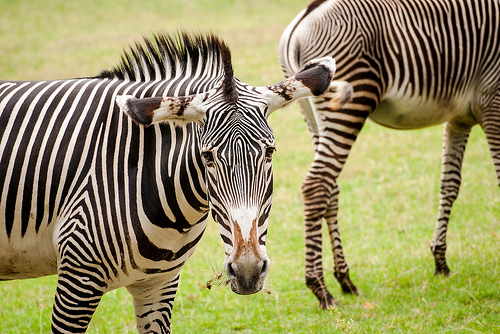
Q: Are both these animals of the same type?
A: Yes, all the animals are zebras.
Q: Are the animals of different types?
A: No, all the animals are zebras.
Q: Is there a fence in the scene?
A: No, there are no fences.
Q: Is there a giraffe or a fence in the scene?
A: No, there are no fences or giraffes.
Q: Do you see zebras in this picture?
A: Yes, there is a zebra.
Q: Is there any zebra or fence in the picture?
A: Yes, there is a zebra.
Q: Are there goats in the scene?
A: No, there are no goats.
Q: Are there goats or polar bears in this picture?
A: No, there are no goats or polar bears.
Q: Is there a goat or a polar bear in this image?
A: No, there are no goats or polar bears.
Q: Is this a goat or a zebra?
A: This is a zebra.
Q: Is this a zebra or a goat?
A: This is a zebra.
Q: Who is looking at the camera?
A: The zebra is looking at the camera.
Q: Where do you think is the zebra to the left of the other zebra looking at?
A: The zebra is looking at the camera.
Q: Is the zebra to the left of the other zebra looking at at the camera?
A: Yes, the zebra is looking at the camera.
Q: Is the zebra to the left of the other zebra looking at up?
A: No, the zebra is looking at the camera.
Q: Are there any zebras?
A: Yes, there is a zebra.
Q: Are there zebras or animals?
A: Yes, there is a zebra.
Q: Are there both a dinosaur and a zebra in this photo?
A: No, there is a zebra but no dinosaurs.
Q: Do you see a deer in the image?
A: No, there is no deer.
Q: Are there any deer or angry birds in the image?
A: No, there are no deer or angry birds.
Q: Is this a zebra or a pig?
A: This is a zebra.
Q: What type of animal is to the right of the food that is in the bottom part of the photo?
A: The animal is a zebra.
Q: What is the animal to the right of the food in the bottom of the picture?
A: The animal is a zebra.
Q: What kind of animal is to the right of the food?
A: The animal is a zebra.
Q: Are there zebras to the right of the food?
A: Yes, there is a zebra to the right of the food.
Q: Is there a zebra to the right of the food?
A: Yes, there is a zebra to the right of the food.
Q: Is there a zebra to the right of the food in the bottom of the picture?
A: Yes, there is a zebra to the right of the food.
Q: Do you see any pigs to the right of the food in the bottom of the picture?
A: No, there is a zebra to the right of the food.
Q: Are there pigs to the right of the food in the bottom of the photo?
A: No, there is a zebra to the right of the food.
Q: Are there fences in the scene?
A: No, there are no fences.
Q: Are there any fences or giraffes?
A: No, there are no fences or giraffes.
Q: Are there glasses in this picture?
A: No, there are no glasses.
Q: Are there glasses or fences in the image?
A: No, there are no glasses or fences.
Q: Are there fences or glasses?
A: No, there are no glasses or fences.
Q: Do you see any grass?
A: Yes, there is grass.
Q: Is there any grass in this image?
A: Yes, there is grass.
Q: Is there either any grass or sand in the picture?
A: Yes, there is grass.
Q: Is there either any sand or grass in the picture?
A: Yes, there is grass.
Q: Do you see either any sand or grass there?
A: Yes, there is grass.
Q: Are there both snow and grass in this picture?
A: No, there is grass but no snow.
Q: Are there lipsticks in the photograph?
A: No, there are no lipsticks.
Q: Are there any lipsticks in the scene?
A: No, there are no lipsticks.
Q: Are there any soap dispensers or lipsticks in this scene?
A: No, there are no lipsticks or soap dispensers.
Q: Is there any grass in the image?
A: Yes, there is grass.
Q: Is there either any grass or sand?
A: Yes, there is grass.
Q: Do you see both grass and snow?
A: No, there is grass but no snow.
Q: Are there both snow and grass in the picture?
A: No, there is grass but no snow.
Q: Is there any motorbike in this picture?
A: No, there are no motorcycles.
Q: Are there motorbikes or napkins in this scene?
A: No, there are no motorbikes or napkins.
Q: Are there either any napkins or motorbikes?
A: No, there are no motorbikes or napkins.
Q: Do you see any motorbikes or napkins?
A: No, there are no motorbikes or napkins.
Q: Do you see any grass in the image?
A: Yes, there is grass.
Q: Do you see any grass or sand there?
A: Yes, there is grass.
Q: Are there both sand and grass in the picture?
A: No, there is grass but no sand.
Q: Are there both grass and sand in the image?
A: No, there is grass but no sand.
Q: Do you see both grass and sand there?
A: No, there is grass but no sand.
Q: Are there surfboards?
A: No, there are no surfboards.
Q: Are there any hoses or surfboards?
A: No, there are no surfboards or hoses.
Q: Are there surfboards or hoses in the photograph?
A: No, there are no surfboards or hoses.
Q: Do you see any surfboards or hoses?
A: No, there are no surfboards or hoses.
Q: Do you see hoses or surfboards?
A: No, there are no surfboards or hoses.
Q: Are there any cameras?
A: Yes, there is a camera.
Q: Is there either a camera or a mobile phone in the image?
A: Yes, there is a camera.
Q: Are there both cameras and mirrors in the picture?
A: No, there is a camera but no mirrors.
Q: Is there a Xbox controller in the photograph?
A: No, there are no Xbox controllers.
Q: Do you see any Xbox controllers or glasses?
A: No, there are no Xbox controllers or glasses.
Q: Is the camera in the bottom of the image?
A: Yes, the camera is in the bottom of the image.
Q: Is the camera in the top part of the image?
A: No, the camera is in the bottom of the image.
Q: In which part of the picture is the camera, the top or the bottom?
A: The camera is in the bottom of the image.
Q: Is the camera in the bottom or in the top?
A: The camera is in the bottom of the image.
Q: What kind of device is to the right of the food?
A: The device is a camera.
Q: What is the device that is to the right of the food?
A: The device is a camera.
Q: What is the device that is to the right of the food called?
A: The device is a camera.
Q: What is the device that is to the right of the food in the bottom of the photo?
A: The device is a camera.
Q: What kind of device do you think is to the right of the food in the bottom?
A: The device is a camera.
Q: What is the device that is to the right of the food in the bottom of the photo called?
A: The device is a camera.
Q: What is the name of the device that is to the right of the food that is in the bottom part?
A: The device is a camera.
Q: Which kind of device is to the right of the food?
A: The device is a camera.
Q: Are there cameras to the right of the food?
A: Yes, there is a camera to the right of the food.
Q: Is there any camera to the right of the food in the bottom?
A: Yes, there is a camera to the right of the food.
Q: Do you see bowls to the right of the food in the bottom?
A: No, there is a camera to the right of the food.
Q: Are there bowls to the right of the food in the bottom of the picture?
A: No, there is a camera to the right of the food.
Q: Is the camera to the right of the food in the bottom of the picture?
A: Yes, the camera is to the right of the food.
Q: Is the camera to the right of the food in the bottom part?
A: Yes, the camera is to the right of the food.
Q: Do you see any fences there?
A: No, there are no fences.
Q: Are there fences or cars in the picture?
A: No, there are no fences or cars.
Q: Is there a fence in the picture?
A: No, there are no fences.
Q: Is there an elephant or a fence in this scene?
A: No, there are no fences or elephants.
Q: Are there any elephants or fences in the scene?
A: No, there are no fences or elephants.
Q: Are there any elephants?
A: No, there are no elephants.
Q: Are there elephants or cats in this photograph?
A: No, there are no elephants or cats.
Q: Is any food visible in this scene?
A: Yes, there is food.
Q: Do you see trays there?
A: No, there are no trays.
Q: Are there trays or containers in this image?
A: No, there are no trays or containers.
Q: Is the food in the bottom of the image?
A: Yes, the food is in the bottom of the image.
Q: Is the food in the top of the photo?
A: No, the food is in the bottom of the image.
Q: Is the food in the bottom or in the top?
A: The food is in the bottom of the image.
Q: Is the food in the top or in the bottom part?
A: The food is in the bottom of the image.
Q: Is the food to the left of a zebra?
A: Yes, the food is to the left of a zebra.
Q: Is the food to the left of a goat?
A: No, the food is to the left of a zebra.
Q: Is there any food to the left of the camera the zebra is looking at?
A: Yes, there is food to the left of the camera.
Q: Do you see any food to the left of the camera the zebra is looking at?
A: Yes, there is food to the left of the camera.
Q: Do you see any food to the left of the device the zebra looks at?
A: Yes, there is food to the left of the camera.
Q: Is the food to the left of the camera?
A: Yes, the food is to the left of the camera.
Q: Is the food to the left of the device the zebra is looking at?
A: Yes, the food is to the left of the camera.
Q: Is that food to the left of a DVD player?
A: No, the food is to the left of the camera.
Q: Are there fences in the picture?
A: No, there are no fences.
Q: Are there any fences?
A: No, there are no fences.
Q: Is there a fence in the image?
A: No, there are no fences.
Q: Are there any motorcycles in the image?
A: No, there are no motorcycles.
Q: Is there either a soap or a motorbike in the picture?
A: No, there are no motorcycles or soaps.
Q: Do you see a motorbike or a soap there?
A: No, there are no motorcycles or soaps.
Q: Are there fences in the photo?
A: No, there are no fences.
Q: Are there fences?
A: No, there are no fences.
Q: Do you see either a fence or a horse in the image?
A: No, there are no fences or horses.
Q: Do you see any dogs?
A: No, there are no dogs.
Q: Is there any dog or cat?
A: No, there are no dogs or cats.